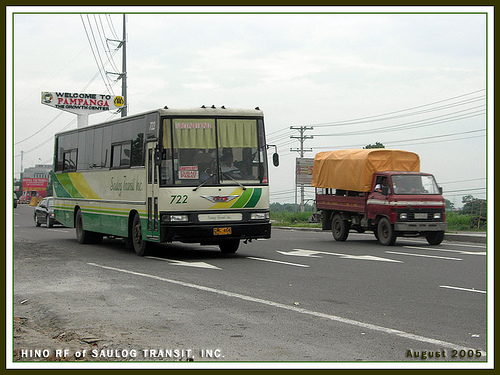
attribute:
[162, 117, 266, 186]
windshield — large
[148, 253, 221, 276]
arrow sign — white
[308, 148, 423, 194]
canopy — orange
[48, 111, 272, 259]
bus — yellow, white, green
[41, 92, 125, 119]
pampanga sign — white, black, red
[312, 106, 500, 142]
power lines — electrical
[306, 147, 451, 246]
truck — brown, red, orange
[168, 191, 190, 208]
number 722 — green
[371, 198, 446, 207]
stripe — white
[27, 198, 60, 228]
car — small, black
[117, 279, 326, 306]
lines — white